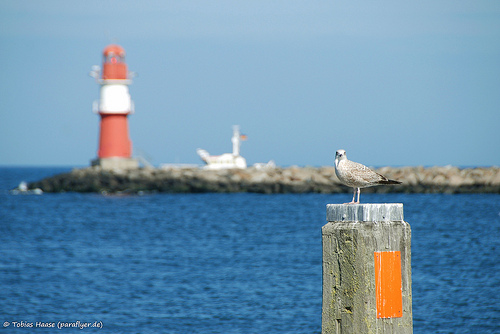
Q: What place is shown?
A: It is an ocean.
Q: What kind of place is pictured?
A: It is an ocean.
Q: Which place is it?
A: It is an ocean.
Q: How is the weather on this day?
A: It is clear.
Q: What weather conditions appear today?
A: It is clear.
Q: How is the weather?
A: It is clear.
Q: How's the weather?
A: It is clear.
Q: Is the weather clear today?
A: Yes, it is clear.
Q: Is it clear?
A: Yes, it is clear.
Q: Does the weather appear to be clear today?
A: Yes, it is clear.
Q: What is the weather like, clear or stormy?
A: It is clear.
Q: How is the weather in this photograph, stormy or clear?
A: It is clear.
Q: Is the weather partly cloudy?
A: No, it is clear.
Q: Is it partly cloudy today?
A: No, it is clear.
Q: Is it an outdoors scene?
A: Yes, it is outdoors.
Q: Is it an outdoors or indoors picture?
A: It is outdoors.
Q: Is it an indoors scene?
A: No, it is outdoors.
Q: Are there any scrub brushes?
A: No, there are no scrub brushes.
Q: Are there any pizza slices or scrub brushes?
A: No, there are no scrub brushes or pizza slices.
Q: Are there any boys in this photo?
A: No, there are no boys.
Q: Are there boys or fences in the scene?
A: No, there are no boys or fences.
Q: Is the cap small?
A: Yes, the cap is small.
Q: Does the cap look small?
A: Yes, the cap is small.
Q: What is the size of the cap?
A: The cap is small.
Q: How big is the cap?
A: The cap is small.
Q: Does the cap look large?
A: No, the cap is small.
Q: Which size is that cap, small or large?
A: The cap is small.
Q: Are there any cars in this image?
A: No, there are no cars.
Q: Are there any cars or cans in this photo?
A: No, there are no cars or cans.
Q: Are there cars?
A: No, there are no cars.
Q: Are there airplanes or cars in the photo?
A: No, there are no cars or airplanes.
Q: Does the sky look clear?
A: Yes, the sky is clear.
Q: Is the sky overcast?
A: No, the sky is clear.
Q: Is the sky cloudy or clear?
A: The sky is clear.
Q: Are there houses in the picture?
A: No, there are no houses.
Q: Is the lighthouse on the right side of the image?
A: No, the lighthouse is on the left of the image.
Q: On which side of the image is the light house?
A: The light house is on the left of the image.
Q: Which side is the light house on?
A: The light house is on the left of the image.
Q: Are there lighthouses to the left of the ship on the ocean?
A: Yes, there is a lighthouse to the left of the ship.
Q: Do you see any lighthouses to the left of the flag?
A: Yes, there is a lighthouse to the left of the flag.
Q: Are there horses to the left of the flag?
A: No, there is a lighthouse to the left of the flag.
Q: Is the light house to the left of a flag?
A: Yes, the light house is to the left of a flag.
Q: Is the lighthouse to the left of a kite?
A: No, the lighthouse is to the left of a flag.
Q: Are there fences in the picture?
A: No, there are no fences.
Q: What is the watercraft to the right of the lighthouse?
A: The watercraft is a ship.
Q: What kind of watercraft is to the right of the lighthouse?
A: The watercraft is a ship.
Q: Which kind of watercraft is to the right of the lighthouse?
A: The watercraft is a ship.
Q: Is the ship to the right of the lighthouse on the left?
A: Yes, the ship is to the right of the light house.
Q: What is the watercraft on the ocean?
A: The watercraft is a ship.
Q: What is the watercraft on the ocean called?
A: The watercraft is a ship.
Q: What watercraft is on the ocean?
A: The watercraft is a ship.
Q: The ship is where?
A: The ship is on the ocean.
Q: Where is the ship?
A: The ship is on the ocean.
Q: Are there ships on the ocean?
A: Yes, there is a ship on the ocean.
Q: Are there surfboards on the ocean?
A: No, there is a ship on the ocean.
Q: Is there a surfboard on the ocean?
A: No, there is a ship on the ocean.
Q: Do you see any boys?
A: No, there are no boys.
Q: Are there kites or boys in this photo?
A: No, there are no boys or kites.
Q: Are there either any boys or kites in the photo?
A: No, there are no boys or kites.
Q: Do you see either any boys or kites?
A: No, there are no boys or kites.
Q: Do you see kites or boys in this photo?
A: No, there are no boys or kites.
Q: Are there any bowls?
A: No, there are no bowls.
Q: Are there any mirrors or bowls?
A: No, there are no bowls or mirrors.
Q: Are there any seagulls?
A: Yes, there is a seagull.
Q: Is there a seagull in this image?
A: Yes, there is a seagull.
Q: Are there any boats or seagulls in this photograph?
A: Yes, there is a seagull.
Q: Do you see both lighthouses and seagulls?
A: Yes, there are both a seagull and a lighthouse.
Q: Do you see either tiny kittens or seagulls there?
A: Yes, there is a tiny seagull.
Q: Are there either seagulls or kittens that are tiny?
A: Yes, the seagull is tiny.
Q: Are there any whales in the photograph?
A: No, there are no whales.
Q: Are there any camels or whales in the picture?
A: No, there are no whales or camels.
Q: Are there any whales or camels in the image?
A: No, there are no whales or camels.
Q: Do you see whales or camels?
A: No, there are no whales or camels.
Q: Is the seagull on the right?
A: Yes, the seagull is on the right of the image.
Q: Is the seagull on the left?
A: No, the seagull is on the right of the image.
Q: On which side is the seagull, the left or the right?
A: The seagull is on the right of the image.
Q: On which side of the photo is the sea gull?
A: The sea gull is on the right of the image.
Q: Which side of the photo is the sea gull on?
A: The sea gull is on the right of the image.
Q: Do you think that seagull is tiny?
A: Yes, the seagull is tiny.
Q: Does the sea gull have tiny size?
A: Yes, the sea gull is tiny.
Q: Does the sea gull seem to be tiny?
A: Yes, the sea gull is tiny.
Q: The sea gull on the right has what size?
A: The seagull is tiny.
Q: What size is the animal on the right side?
A: The seagull is tiny.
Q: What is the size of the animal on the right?
A: The seagull is tiny.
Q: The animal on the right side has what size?
A: The seagull is tiny.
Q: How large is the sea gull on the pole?
A: The seagull is tiny.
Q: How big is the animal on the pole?
A: The seagull is tiny.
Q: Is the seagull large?
A: No, the seagull is tiny.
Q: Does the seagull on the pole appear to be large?
A: No, the sea gull is tiny.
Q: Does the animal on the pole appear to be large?
A: No, the sea gull is tiny.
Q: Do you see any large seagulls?
A: No, there is a seagull but it is tiny.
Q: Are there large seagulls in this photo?
A: No, there is a seagull but it is tiny.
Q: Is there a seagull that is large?
A: No, there is a seagull but it is tiny.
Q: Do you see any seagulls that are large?
A: No, there is a seagull but it is tiny.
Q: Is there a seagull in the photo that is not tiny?
A: No, there is a seagull but it is tiny.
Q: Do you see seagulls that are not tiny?
A: No, there is a seagull but it is tiny.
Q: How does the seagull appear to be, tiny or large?
A: The seagull is tiny.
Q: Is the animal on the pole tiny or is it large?
A: The seagull is tiny.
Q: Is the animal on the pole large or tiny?
A: The seagull is tiny.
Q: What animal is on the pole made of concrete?
A: The seagull is on the pole.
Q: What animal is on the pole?
A: The seagull is on the pole.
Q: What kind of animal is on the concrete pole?
A: The animal is a seagull.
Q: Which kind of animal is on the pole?
A: The animal is a seagull.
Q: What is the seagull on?
A: The seagull is on the pole.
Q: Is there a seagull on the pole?
A: Yes, there is a seagull on the pole.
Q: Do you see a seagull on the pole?
A: Yes, there is a seagull on the pole.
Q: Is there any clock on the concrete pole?
A: No, there is a seagull on the pole.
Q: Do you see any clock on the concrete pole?
A: No, there is a seagull on the pole.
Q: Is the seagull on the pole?
A: Yes, the seagull is on the pole.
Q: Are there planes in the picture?
A: No, there are no planes.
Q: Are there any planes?
A: No, there are no planes.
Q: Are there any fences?
A: No, there are no fences.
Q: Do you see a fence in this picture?
A: No, there are no fences.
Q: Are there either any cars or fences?
A: No, there are no fences or cars.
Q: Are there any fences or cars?
A: No, there are no fences or cars.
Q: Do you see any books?
A: No, there are no books.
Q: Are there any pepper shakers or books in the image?
A: No, there are no books or pepper shakers.